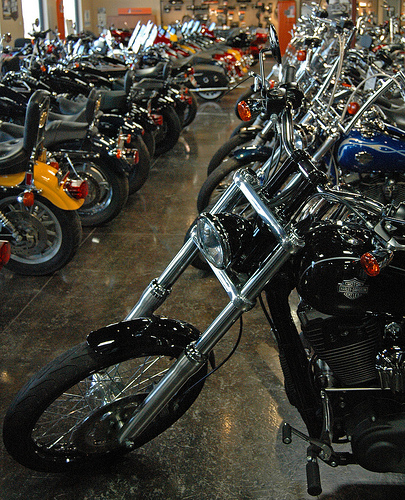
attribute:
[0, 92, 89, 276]
motorcycle — yellow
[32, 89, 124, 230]
motorcycle — black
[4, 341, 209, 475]
tire — black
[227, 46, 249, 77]
back — yellow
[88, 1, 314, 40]
wall — orange, in back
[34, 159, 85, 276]
back — yellow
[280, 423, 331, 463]
stick — kick stick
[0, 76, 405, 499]
floor — black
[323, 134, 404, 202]
motorcycle — blue, silver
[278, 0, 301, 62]
door — orange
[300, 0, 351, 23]
mirror — reflecting 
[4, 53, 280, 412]
isle — narrow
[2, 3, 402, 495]
motorcycle — parked , black, gray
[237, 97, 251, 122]
light — orange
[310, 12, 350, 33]
handles — chrome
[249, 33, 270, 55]
bike — red